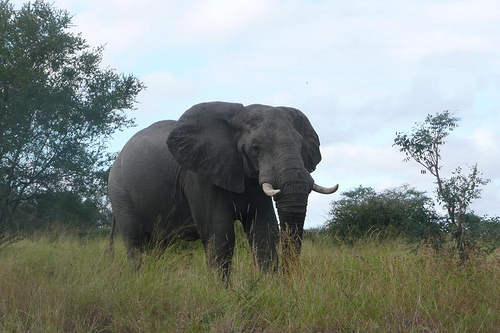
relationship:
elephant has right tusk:
[104, 100, 339, 290] [261, 182, 281, 197]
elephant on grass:
[104, 100, 339, 290] [2, 252, 498, 322]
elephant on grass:
[104, 100, 339, 290] [165, 261, 412, 326]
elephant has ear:
[104, 100, 339, 290] [164, 100, 247, 194]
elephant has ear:
[85, 97, 344, 294] [162, 93, 244, 195]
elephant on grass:
[104, 100, 339, 290] [1, 223, 497, 330]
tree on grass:
[392, 103, 492, 261] [4, 241, 497, 332]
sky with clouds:
[0, 2, 498, 232] [4, 0, 499, 220]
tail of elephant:
[76, 194, 129, 251] [104, 100, 339, 290]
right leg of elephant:
[193, 207, 234, 290] [104, 100, 339, 290]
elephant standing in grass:
[104, 100, 339, 290] [1, 223, 497, 330]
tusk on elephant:
[308, 180, 345, 198] [104, 100, 339, 290]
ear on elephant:
[164, 101, 247, 195] [104, 100, 339, 290]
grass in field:
[1, 232, 491, 331] [1, 221, 497, 325]